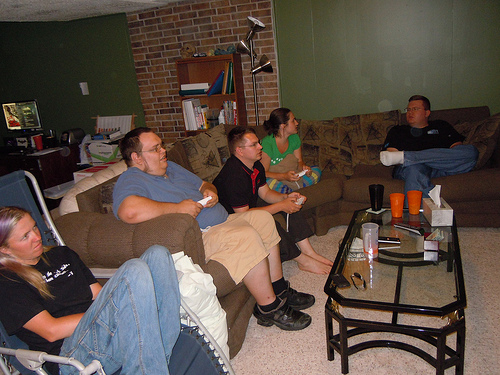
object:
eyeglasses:
[130, 142, 165, 152]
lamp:
[231, 14, 275, 129]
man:
[107, 130, 316, 329]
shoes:
[251, 279, 315, 331]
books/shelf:
[175, 54, 241, 129]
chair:
[0, 167, 235, 374]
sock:
[379, 151, 406, 167]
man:
[379, 90, 479, 191]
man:
[206, 124, 306, 217]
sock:
[254, 296, 284, 313]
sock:
[271, 275, 291, 294]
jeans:
[49, 241, 179, 374]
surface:
[328, 201, 471, 313]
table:
[319, 199, 475, 374]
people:
[2, 95, 475, 375]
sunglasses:
[350, 272, 370, 293]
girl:
[260, 108, 325, 193]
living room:
[1, 0, 499, 375]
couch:
[0, 107, 499, 372]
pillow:
[301, 118, 353, 172]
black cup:
[368, 185, 384, 212]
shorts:
[202, 208, 283, 285]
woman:
[1, 204, 185, 374]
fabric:
[0, 107, 500, 373]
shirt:
[112, 158, 229, 229]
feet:
[255, 272, 315, 334]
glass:
[329, 205, 464, 322]